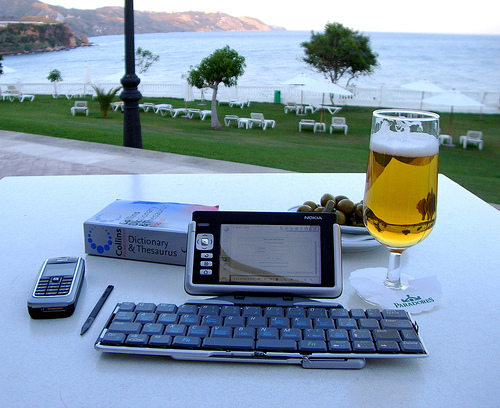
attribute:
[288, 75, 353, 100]
umbrellas — white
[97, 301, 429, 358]
keyboard — small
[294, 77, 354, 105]
umbrella — white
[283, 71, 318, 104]
umbrella — white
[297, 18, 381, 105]
tree — green